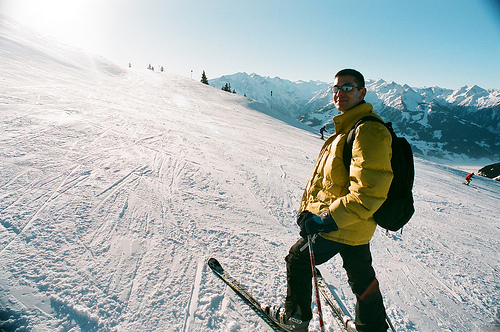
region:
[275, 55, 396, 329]
skier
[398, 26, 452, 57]
white clouds in blue sky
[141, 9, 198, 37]
white clouds in blue sky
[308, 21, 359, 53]
white clouds in blue sky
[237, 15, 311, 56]
white clouds in blue sky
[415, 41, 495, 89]
white clouds in blue sky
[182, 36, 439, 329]
this man is skiing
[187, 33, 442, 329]
he is walking up a slope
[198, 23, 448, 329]
he is walking with skis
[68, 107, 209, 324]
there are tracks in the snow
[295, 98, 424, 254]
a big puffy jacket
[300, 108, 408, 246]
the jacket is bright yellow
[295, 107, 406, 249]
a yellow down jacket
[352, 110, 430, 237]
this is a black backpack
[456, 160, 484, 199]
a person skiing down the mountain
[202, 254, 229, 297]
edge of a board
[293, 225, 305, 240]
part of a glove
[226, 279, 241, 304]
edge of a board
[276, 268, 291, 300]
par tof a guad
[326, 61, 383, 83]
The man has dark hair.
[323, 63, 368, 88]
The mans hair is brown.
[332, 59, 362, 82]
The mans hair is short.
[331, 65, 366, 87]
The mans hair is straight.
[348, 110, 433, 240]
The man is carrying a backpack.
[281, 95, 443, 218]
The man is wearing a yellow jacket.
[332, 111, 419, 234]
The mans backpack is full.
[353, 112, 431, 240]
The mans backpack is black.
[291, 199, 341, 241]
The man is wearing gloves.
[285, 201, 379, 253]
The mans gloves are black.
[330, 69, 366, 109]
a man is smiling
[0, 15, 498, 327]
snow all over the place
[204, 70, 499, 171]
mountains in the distance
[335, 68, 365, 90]
the hair is dark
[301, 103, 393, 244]
the jacket is yellow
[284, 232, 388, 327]
the pants are dark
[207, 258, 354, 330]
a pair of skiis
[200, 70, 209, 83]
a lone pine tree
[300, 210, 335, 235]
the gloves are black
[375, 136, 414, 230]
the backpack is black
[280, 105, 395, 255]
puffy yellow jacket with collar